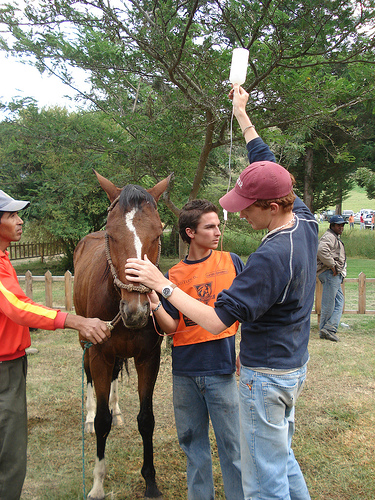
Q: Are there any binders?
A: No, there are no binders.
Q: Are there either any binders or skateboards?
A: No, there are no binders or skateboards.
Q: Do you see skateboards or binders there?
A: No, there are no binders or skateboards.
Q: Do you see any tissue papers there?
A: No, there are no tissue papers.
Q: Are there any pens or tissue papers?
A: No, there are no tissue papers or pens.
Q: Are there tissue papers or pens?
A: No, there are no tissue papers or pens.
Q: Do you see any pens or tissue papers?
A: No, there are no tissue papers or pens.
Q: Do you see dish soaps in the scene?
A: No, there are no dish soaps.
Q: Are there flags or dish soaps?
A: No, there are no dish soaps or flags.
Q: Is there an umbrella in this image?
A: No, there are no umbrellas.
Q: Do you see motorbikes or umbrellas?
A: No, there are no umbrellas or motorbikes.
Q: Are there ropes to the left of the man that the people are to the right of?
A: Yes, there is a rope to the left of the man.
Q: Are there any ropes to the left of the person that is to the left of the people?
A: Yes, there is a rope to the left of the man.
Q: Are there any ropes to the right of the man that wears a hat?
A: No, the rope is to the left of the man.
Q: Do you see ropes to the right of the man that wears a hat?
A: No, the rope is to the left of the man.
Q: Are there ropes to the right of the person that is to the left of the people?
A: No, the rope is to the left of the man.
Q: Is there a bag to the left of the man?
A: No, there is a rope to the left of the man.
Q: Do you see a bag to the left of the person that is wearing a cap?
A: No, there is a rope to the left of the man.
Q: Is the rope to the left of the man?
A: Yes, the rope is to the left of the man.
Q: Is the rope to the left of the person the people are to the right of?
A: Yes, the rope is to the left of the man.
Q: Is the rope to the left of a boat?
A: No, the rope is to the left of the man.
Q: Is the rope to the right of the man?
A: No, the rope is to the left of the man.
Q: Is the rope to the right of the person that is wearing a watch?
A: No, the rope is to the left of the man.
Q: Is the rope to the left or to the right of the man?
A: The rope is to the left of the man.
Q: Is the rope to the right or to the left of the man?
A: The rope is to the left of the man.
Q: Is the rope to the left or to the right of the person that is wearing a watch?
A: The rope is to the left of the man.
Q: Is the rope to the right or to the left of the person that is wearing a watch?
A: The rope is to the left of the man.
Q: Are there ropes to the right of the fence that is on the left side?
A: Yes, there is a rope to the right of the fence.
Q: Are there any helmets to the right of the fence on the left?
A: No, there is a rope to the right of the fence.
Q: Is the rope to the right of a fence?
A: Yes, the rope is to the right of a fence.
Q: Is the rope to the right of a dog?
A: No, the rope is to the right of a fence.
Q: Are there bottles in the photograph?
A: Yes, there is a bottle.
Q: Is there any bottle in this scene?
A: Yes, there is a bottle.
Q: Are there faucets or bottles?
A: Yes, there is a bottle.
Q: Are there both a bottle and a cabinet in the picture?
A: No, there is a bottle but no cabinets.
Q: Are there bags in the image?
A: No, there are no bags.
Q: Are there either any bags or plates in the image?
A: No, there are no bags or plates.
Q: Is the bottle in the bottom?
A: No, the bottle is in the top of the image.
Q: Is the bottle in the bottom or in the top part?
A: The bottle is in the top of the image.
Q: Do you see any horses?
A: Yes, there is a horse.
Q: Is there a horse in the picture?
A: Yes, there is a horse.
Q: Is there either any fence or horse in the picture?
A: Yes, there is a horse.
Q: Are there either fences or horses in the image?
A: Yes, there is a horse.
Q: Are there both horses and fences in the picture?
A: Yes, there are both a horse and a fence.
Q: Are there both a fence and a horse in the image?
A: Yes, there are both a horse and a fence.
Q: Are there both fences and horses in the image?
A: Yes, there are both a horse and a fence.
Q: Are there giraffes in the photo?
A: No, there are no giraffes.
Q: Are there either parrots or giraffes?
A: No, there are no giraffes or parrots.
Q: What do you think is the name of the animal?
A: The animal is a horse.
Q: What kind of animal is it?
A: The animal is a horse.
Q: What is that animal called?
A: This is a horse.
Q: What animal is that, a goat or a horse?
A: This is a horse.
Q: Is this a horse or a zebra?
A: This is a horse.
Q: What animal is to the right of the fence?
A: The animal is a horse.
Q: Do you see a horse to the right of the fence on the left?
A: Yes, there is a horse to the right of the fence.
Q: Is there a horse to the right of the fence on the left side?
A: Yes, there is a horse to the right of the fence.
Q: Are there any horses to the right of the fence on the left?
A: Yes, there is a horse to the right of the fence.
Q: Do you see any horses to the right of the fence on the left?
A: Yes, there is a horse to the right of the fence.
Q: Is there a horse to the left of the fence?
A: No, the horse is to the right of the fence.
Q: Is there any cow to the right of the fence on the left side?
A: No, there is a horse to the right of the fence.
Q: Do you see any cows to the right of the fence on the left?
A: No, there is a horse to the right of the fence.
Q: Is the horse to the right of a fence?
A: Yes, the horse is to the right of a fence.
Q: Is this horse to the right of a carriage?
A: No, the horse is to the right of a fence.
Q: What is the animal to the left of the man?
A: The animal is a horse.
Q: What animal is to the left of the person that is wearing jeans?
A: The animal is a horse.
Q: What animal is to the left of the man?
A: The animal is a horse.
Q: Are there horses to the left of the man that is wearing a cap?
A: Yes, there is a horse to the left of the man.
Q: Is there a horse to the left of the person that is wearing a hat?
A: Yes, there is a horse to the left of the man.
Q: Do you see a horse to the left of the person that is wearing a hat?
A: Yes, there is a horse to the left of the man.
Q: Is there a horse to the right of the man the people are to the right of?
A: No, the horse is to the left of the man.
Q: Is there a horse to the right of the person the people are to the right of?
A: No, the horse is to the left of the man.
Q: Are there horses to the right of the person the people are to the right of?
A: No, the horse is to the left of the man.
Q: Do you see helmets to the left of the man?
A: No, there is a horse to the left of the man.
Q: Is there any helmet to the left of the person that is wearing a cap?
A: No, there is a horse to the left of the man.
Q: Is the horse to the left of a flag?
A: No, the horse is to the left of the man.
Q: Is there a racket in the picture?
A: No, there are no rackets.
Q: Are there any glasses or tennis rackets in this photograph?
A: No, there are no tennis rackets or glasses.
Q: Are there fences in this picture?
A: Yes, there is a fence.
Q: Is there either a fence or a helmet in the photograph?
A: Yes, there is a fence.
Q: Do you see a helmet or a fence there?
A: Yes, there is a fence.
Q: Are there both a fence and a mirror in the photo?
A: No, there is a fence but no mirrors.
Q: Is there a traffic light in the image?
A: No, there are no traffic lights.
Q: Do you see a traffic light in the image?
A: No, there are no traffic lights.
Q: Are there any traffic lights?
A: No, there are no traffic lights.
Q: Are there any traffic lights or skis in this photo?
A: No, there are no traffic lights or skis.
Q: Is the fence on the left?
A: Yes, the fence is on the left of the image.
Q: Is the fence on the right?
A: No, the fence is on the left of the image.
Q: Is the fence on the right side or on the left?
A: The fence is on the left of the image.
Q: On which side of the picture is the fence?
A: The fence is on the left of the image.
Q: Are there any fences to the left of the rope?
A: Yes, there is a fence to the left of the rope.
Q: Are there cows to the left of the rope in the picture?
A: No, there is a fence to the left of the rope.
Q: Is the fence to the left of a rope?
A: Yes, the fence is to the left of a rope.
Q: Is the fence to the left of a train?
A: No, the fence is to the left of a rope.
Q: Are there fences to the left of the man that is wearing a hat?
A: Yes, there is a fence to the left of the man.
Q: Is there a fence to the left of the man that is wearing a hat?
A: Yes, there is a fence to the left of the man.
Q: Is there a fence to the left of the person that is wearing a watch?
A: Yes, there is a fence to the left of the man.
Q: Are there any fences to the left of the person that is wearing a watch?
A: Yes, there is a fence to the left of the man.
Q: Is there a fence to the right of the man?
A: No, the fence is to the left of the man.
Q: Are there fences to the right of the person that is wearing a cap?
A: No, the fence is to the left of the man.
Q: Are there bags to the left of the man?
A: No, there is a fence to the left of the man.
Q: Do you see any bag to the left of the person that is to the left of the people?
A: No, there is a fence to the left of the man.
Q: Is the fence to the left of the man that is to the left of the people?
A: Yes, the fence is to the left of the man.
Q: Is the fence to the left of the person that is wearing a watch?
A: Yes, the fence is to the left of the man.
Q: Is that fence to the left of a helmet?
A: No, the fence is to the left of the man.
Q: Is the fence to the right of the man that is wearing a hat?
A: No, the fence is to the left of the man.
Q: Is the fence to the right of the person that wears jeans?
A: No, the fence is to the left of the man.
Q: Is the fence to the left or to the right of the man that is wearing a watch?
A: The fence is to the left of the man.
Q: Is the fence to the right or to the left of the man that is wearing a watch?
A: The fence is to the left of the man.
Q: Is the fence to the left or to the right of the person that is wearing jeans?
A: The fence is to the left of the man.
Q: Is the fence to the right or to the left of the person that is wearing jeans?
A: The fence is to the left of the man.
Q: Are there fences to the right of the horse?
A: No, the fence is to the left of the horse.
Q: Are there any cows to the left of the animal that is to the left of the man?
A: No, there is a fence to the left of the horse.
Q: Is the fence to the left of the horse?
A: Yes, the fence is to the left of the horse.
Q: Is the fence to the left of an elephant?
A: No, the fence is to the left of the horse.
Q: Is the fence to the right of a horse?
A: No, the fence is to the left of a horse.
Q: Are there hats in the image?
A: Yes, there is a hat.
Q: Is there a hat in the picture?
A: Yes, there is a hat.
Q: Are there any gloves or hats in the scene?
A: Yes, there is a hat.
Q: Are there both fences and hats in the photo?
A: Yes, there are both a hat and a fence.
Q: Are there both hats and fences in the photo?
A: Yes, there are both a hat and a fence.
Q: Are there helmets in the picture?
A: No, there are no helmets.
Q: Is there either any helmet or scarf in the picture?
A: No, there are no helmets or scarves.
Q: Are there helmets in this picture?
A: No, there are no helmets.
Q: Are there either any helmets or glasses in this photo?
A: No, there are no helmets or glasses.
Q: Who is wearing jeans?
A: The man is wearing jeans.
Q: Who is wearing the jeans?
A: The man is wearing jeans.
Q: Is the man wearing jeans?
A: Yes, the man is wearing jeans.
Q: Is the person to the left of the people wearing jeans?
A: Yes, the man is wearing jeans.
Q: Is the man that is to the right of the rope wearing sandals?
A: No, the man is wearing jeans.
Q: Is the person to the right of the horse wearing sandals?
A: No, the man is wearing jeans.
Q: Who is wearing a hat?
A: The man is wearing a hat.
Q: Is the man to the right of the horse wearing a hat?
A: Yes, the man is wearing a hat.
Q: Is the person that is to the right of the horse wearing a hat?
A: Yes, the man is wearing a hat.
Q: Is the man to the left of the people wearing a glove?
A: No, the man is wearing a hat.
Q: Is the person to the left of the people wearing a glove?
A: No, the man is wearing a hat.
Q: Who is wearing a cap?
A: The man is wearing a cap.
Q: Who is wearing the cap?
A: The man is wearing a cap.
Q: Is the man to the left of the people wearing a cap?
A: Yes, the man is wearing a cap.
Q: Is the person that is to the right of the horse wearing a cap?
A: Yes, the man is wearing a cap.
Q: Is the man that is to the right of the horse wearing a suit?
A: No, the man is wearing a cap.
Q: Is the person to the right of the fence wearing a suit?
A: No, the man is wearing a cap.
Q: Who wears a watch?
A: The man wears a watch.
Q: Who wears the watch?
A: The man wears a watch.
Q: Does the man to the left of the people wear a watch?
A: Yes, the man wears a watch.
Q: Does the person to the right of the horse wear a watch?
A: Yes, the man wears a watch.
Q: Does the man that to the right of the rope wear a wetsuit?
A: No, the man wears a watch.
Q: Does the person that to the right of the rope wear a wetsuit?
A: No, the man wears a watch.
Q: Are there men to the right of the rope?
A: Yes, there is a man to the right of the rope.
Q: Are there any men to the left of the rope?
A: No, the man is to the right of the rope.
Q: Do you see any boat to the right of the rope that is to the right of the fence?
A: No, there is a man to the right of the rope.